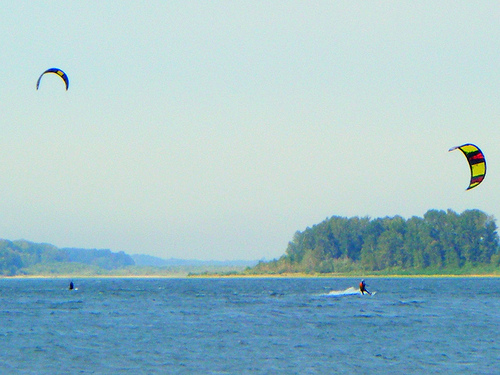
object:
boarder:
[69, 281, 74, 290]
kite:
[35, 68, 69, 91]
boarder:
[358, 279, 378, 297]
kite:
[448, 143, 488, 192]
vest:
[359, 282, 364, 288]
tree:
[284, 224, 315, 265]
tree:
[359, 236, 386, 271]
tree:
[378, 230, 402, 270]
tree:
[477, 220, 500, 245]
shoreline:
[0, 273, 499, 278]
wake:
[326, 286, 368, 295]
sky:
[1, 1, 500, 261]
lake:
[0, 276, 499, 374]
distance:
[1, 208, 500, 278]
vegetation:
[344, 259, 499, 275]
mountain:
[0, 238, 134, 278]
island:
[0, 208, 499, 279]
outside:
[0, 1, 499, 374]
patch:
[286, 208, 500, 276]